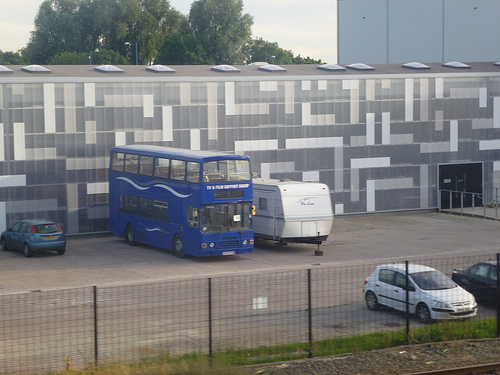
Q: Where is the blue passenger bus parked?
A: In the parking lot.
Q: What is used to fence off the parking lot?
A: A metal fence against grass.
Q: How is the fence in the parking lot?
A: A tall metal fence.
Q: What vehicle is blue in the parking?
A: A tall bus.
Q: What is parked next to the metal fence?
A: A white vehicle.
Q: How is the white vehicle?
A: It is parked.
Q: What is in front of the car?
A: A fence.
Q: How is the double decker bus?
A: It is blue.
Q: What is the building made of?
A: Glass.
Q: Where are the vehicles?
A: Parking lot.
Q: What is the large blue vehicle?
A: Bus.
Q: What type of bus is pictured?
A: Double decker.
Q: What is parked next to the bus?
A: RV.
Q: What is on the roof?
A: Sky lights.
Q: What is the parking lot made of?
A: Asphalt.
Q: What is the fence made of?
A: Metal.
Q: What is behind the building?
A: Tree.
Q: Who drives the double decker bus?
A: Driver.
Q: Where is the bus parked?
A: Parking lot.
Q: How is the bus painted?
A: In blue paint.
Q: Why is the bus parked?
A: Waiting.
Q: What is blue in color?
A: The bus.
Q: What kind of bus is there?
A: Double decker.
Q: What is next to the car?
A: Fence.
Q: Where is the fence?
A: Next to the car.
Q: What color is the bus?
A: Blue.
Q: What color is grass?
A: Green.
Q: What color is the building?
A: White, tan and grey.